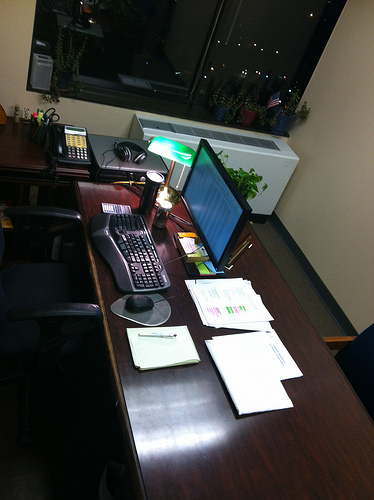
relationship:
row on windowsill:
[208, 72, 311, 135] [27, 82, 291, 137]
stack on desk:
[184, 277, 274, 333] [75, 180, 373, 500]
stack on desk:
[203, 330, 304, 417] [75, 180, 373, 500]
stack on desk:
[125, 325, 201, 372] [75, 180, 373, 500]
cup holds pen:
[27, 119, 48, 146] [36, 107, 41, 118]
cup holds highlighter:
[27, 119, 48, 146] [33, 110, 38, 119]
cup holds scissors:
[27, 119, 48, 146] [40, 108, 61, 123]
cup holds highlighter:
[27, 119, 48, 146] [37, 110, 44, 123]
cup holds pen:
[27, 119, 48, 146] [36, 107, 41, 134]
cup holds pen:
[27, 119, 48, 146] [46, 117, 50, 126]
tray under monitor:
[173, 232, 226, 279] [179, 138, 253, 271]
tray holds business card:
[173, 232, 226, 279] [177, 238, 206, 261]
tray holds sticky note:
[173, 232, 226, 279] [205, 260, 226, 276]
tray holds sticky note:
[173, 232, 226, 279] [195, 260, 218, 276]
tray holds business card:
[173, 232, 226, 279] [177, 238, 187, 251]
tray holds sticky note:
[173, 232, 226, 279] [178, 230, 199, 239]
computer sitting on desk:
[86, 132, 170, 175] [1, 114, 138, 264]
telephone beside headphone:
[46, 122, 93, 193] [115, 140, 149, 164]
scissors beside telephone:
[40, 108, 61, 123] [46, 122, 93, 193]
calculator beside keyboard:
[101, 202, 133, 215] [90, 212, 170, 291]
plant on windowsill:
[40, 23, 89, 104] [27, 82, 291, 137]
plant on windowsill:
[204, 76, 245, 125] [27, 82, 291, 137]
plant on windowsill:
[235, 94, 269, 131] [27, 82, 291, 137]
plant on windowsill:
[266, 88, 311, 135] [27, 82, 291, 137]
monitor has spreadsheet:
[179, 138, 253, 271] [182, 156, 238, 261]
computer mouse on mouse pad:
[125, 294, 154, 315] [109, 292, 173, 326]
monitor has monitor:
[179, 138, 253, 271] [179, 138, 253, 271]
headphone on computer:
[115, 140, 149, 164] [86, 132, 170, 175]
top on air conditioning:
[134, 112, 300, 161] [127, 111, 300, 224]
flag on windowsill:
[266, 89, 280, 109] [27, 82, 291, 137]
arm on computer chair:
[2, 204, 81, 262] [1, 204, 103, 408]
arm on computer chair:
[7, 303, 104, 356] [1, 204, 103, 408]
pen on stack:
[138, 332, 179, 338] [125, 325, 201, 372]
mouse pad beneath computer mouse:
[109, 292, 173, 326] [125, 294, 154, 315]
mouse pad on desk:
[109, 292, 173, 326] [75, 180, 373, 500]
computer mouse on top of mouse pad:
[125, 294, 154, 315] [109, 292, 173, 326]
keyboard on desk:
[90, 212, 170, 291] [75, 180, 373, 500]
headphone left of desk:
[115, 140, 149, 164] [75, 180, 373, 500]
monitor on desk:
[179, 138, 253, 271] [75, 180, 373, 500]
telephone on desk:
[46, 122, 93, 193] [1, 114, 138, 264]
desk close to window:
[1, 114, 138, 264] [26, 0, 347, 139]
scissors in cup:
[40, 108, 61, 123] [27, 119, 48, 146]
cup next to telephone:
[27, 119, 48, 146] [46, 122, 93, 193]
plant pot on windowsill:
[236, 107, 258, 125] [27, 82, 291, 137]